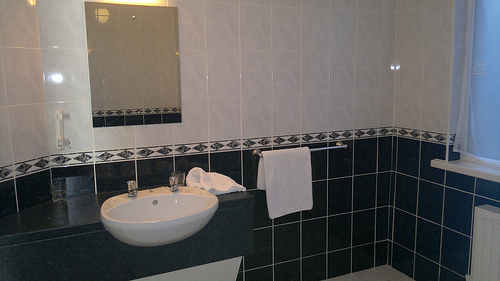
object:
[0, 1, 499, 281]
wall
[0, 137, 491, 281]
black wall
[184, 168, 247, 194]
towel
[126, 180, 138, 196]
water handle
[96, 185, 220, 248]
sink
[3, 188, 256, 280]
gray vanity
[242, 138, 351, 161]
rack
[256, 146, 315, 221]
towel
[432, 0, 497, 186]
window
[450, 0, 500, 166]
curtain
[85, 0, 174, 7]
light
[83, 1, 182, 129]
mirror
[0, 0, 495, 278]
bathroom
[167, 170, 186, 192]
faucet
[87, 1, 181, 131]
reflection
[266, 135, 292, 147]
shapes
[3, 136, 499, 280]
black tile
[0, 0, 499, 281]
tile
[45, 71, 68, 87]
reflection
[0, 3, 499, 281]
lower wall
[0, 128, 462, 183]
border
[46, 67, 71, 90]
light